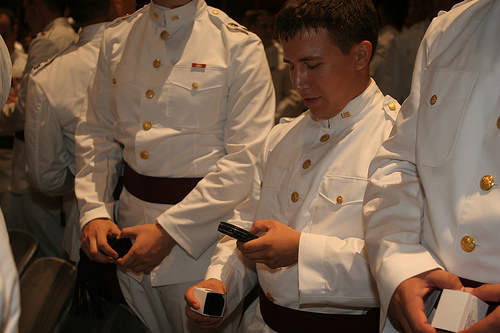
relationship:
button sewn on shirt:
[458, 234, 478, 253] [360, 14, 482, 331]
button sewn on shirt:
[317, 131, 330, 142] [202, 78, 402, 329]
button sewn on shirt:
[300, 157, 310, 170] [202, 78, 402, 329]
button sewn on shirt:
[289, 188, 299, 204] [202, 78, 402, 329]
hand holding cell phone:
[233, 217, 302, 272] [215, 220, 257, 243]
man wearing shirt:
[360, 0, 500, 330] [360, 14, 482, 331]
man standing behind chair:
[20, 0, 140, 304] [6, 226, 40, 279]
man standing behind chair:
[72, 0, 280, 333] [6, 226, 40, 279]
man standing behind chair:
[360, 0, 500, 330] [17, 252, 79, 331]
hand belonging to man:
[112, 220, 173, 275] [72, 0, 280, 333]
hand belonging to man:
[78, 215, 124, 265] [72, 0, 280, 333]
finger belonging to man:
[116, 244, 136, 269] [72, 0, 280, 333]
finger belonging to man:
[426, 265, 465, 294] [360, 0, 500, 330]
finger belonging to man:
[399, 279, 437, 331] [360, 0, 500, 330]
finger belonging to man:
[93, 229, 119, 259] [72, 0, 280, 333]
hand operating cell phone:
[233, 217, 298, 271] [213, 219, 258, 243]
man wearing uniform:
[20, 1, 140, 266] [21, 21, 114, 264]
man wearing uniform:
[72, 1, 276, 331] [71, 0, 274, 330]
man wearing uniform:
[360, 0, 485, 330] [359, 1, 481, 331]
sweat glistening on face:
[285, 28, 328, 90] [280, 22, 352, 119]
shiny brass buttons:
[427, 218, 495, 283] [439, 171, 493, 260]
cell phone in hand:
[215, 220, 241, 241] [252, 214, 330, 320]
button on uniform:
[290, 190, 299, 203] [272, 180, 347, 276]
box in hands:
[432, 294, 463, 333] [362, 302, 499, 333]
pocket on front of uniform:
[163, 64, 218, 134] [104, 103, 205, 219]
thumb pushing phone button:
[244, 214, 264, 237] [210, 205, 271, 310]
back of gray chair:
[39, 295, 79, 333] [14, 234, 144, 333]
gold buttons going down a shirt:
[134, 52, 174, 169] [177, 122, 209, 139]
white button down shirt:
[224, 172, 264, 212] [74, 54, 181, 217]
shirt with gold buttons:
[32, 116, 200, 310] [142, 118, 160, 163]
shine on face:
[303, 36, 323, 55] [277, 25, 362, 122]